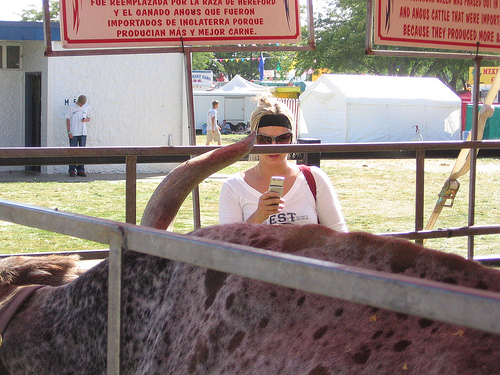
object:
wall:
[45, 53, 183, 174]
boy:
[204, 100, 222, 146]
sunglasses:
[255, 132, 292, 145]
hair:
[247, 97, 295, 172]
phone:
[266, 176, 284, 205]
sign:
[59, 0, 301, 49]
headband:
[253, 113, 293, 130]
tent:
[292, 74, 462, 141]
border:
[61, 39, 301, 48]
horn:
[140, 129, 256, 230]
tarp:
[296, 74, 463, 142]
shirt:
[64, 102, 92, 135]